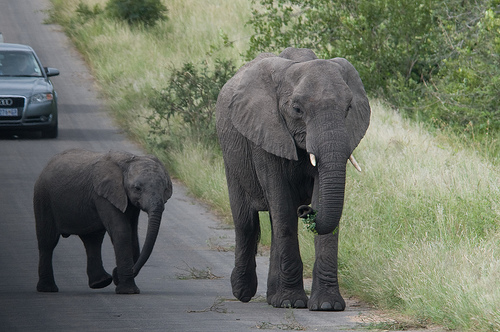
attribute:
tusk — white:
[345, 150, 367, 172]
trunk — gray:
[107, 207, 179, 294]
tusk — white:
[339, 147, 373, 182]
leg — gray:
[269, 200, 309, 306]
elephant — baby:
[23, 139, 179, 297]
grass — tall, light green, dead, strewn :
[53, 0, 495, 330]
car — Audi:
[0, 40, 62, 145]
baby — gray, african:
[28, 143, 179, 300]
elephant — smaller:
[187, 16, 419, 315]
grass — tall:
[363, 173, 499, 329]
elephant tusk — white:
[187, 45, 410, 295]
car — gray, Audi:
[2, 40, 65, 135]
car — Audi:
[0, 43, 62, 135]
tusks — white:
[303, 145, 370, 179]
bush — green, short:
[302, 2, 499, 127]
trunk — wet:
[132, 190, 163, 285]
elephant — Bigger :
[187, 53, 411, 320]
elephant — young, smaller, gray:
[32, 147, 172, 293]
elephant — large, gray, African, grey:
[210, 45, 370, 312]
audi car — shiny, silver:
[1, 33, 66, 138]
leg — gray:
[227, 200, 257, 300]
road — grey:
[1, 1, 426, 330]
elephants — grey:
[33, 145, 172, 295]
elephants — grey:
[213, 47, 374, 312]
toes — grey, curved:
[308, 288, 355, 310]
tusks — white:
[305, 147, 326, 175]